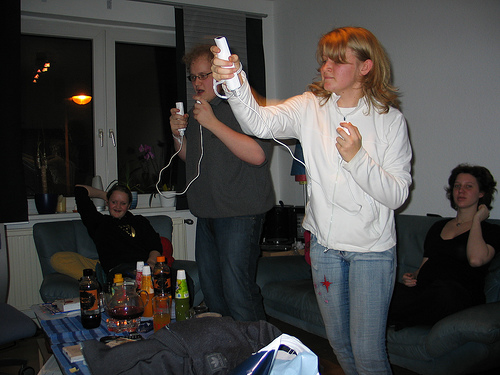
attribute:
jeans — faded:
[301, 220, 428, 374]